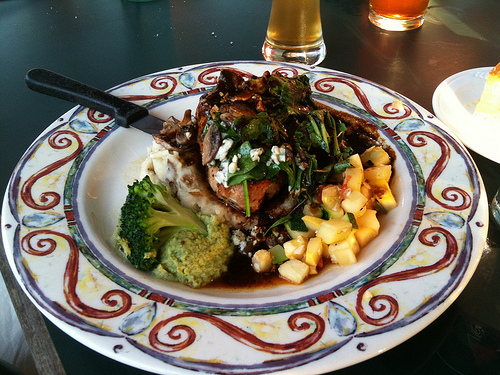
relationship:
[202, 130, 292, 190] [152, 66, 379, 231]
mushrooms on steak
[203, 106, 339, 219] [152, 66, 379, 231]
mushrooms on steak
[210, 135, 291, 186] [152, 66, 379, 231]
feta on steak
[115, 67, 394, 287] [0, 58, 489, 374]
food on plate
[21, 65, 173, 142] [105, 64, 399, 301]
knife in food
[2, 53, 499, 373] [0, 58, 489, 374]
designs on plate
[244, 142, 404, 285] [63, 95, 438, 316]
chopped food on plate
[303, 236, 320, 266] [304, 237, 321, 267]
piece of potatoe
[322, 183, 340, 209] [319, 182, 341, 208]
piece of potatoe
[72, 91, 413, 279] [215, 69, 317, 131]
meal with meat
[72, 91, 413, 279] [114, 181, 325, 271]
meal with veggies